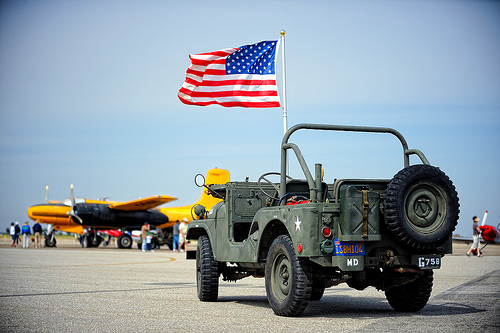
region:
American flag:
[177, 31, 282, 116]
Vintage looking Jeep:
[183, 118, 460, 317]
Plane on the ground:
[22, 162, 229, 284]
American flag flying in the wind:
[172, 21, 290, 123]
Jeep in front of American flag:
[173, 19, 460, 319]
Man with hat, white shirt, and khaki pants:
[177, 213, 188, 250]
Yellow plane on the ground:
[23, 163, 235, 266]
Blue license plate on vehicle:
[331, 235, 371, 262]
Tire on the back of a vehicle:
[371, 159, 470, 266]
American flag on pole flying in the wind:
[172, 24, 292, 142]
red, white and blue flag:
[176, 38, 281, 110]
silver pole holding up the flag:
[277, 25, 287, 145]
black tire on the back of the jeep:
[380, 161, 460, 248]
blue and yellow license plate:
[330, 235, 366, 255]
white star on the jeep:
[290, 211, 305, 231]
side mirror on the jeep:
[191, 170, 217, 195]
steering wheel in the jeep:
[255, 167, 292, 202]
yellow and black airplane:
[26, 165, 230, 252]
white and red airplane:
[471, 210, 499, 254]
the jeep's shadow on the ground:
[212, 293, 486, 320]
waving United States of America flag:
[174, 34, 284, 114]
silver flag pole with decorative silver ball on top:
[276, 20, 293, 183]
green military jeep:
[179, 119, 462, 324]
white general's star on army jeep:
[280, 207, 311, 237]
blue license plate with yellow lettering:
[326, 236, 366, 256]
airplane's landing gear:
[82, 226, 136, 251]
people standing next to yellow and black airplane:
[5, 214, 61, 251]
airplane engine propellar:
[62, 183, 88, 230]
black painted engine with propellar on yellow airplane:
[57, 183, 169, 231]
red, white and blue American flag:
[178, 38, 283, 110]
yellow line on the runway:
[0, 248, 180, 271]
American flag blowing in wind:
[181, 28, 283, 118]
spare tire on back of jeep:
[387, 162, 477, 244]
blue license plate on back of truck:
[336, 241, 372, 260]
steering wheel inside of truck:
[255, 171, 292, 208]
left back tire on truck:
[262, 238, 308, 330]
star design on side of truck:
[290, 213, 307, 238]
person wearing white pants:
[469, 211, 488, 253]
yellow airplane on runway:
[27, 164, 228, 233]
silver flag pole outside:
[280, 26, 290, 128]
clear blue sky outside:
[26, 14, 159, 109]